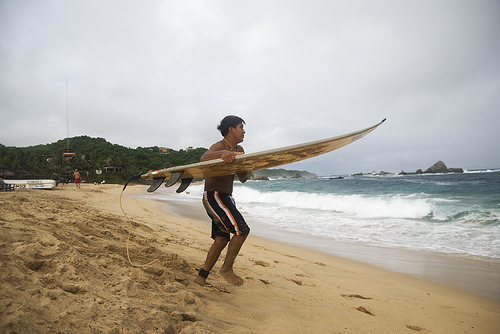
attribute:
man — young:
[200, 113, 251, 290]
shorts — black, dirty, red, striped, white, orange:
[201, 189, 253, 236]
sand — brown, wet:
[4, 180, 499, 331]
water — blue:
[185, 168, 497, 262]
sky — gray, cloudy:
[1, 1, 499, 177]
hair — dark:
[215, 114, 246, 136]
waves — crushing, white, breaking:
[252, 183, 477, 227]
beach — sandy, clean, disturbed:
[9, 171, 499, 333]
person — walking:
[72, 164, 84, 186]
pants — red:
[73, 176, 82, 180]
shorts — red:
[74, 176, 83, 183]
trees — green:
[0, 135, 224, 180]